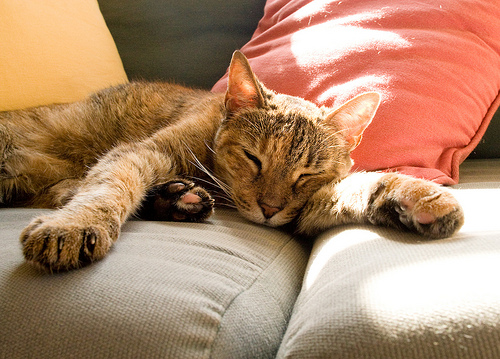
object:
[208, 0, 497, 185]
pillow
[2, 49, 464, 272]
cat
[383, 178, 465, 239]
paw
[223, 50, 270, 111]
ear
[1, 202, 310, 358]
cushion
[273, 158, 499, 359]
cushion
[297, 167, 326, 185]
right eye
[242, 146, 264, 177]
left eye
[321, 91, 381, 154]
right ear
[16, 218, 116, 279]
paw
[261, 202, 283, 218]
nose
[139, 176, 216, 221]
back paw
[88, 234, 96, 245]
claw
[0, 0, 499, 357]
couch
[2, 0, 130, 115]
pillow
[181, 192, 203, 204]
toe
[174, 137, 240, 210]
whisker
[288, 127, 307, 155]
stripe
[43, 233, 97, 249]
nails